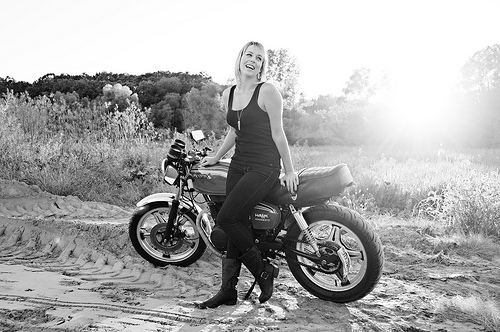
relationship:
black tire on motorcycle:
[285, 201, 383, 303] [127, 128, 384, 304]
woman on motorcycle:
[194, 38, 301, 309] [127, 128, 384, 304]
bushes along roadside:
[1, 82, 176, 195] [0, 178, 499, 330]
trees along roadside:
[1, 47, 498, 129] [0, 178, 499, 330]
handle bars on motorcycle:
[162, 138, 202, 180] [127, 128, 384, 304]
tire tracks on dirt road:
[3, 224, 193, 300] [2, 217, 492, 329]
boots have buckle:
[242, 260, 278, 294] [260, 265, 270, 280]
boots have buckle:
[205, 258, 237, 310] [260, 265, 270, 280]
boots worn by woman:
[242, 260, 278, 294] [204, 34, 304, 314]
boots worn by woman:
[205, 258, 237, 310] [204, 34, 304, 314]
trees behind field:
[5, 71, 227, 132] [287, 99, 497, 204]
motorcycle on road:
[127, 128, 384, 304] [4, 185, 498, 330]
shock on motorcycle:
[288, 206, 320, 260] [127, 128, 384, 304]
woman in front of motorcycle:
[194, 38, 301, 309] [127, 128, 384, 304]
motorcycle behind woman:
[127, 128, 384, 304] [194, 38, 301, 309]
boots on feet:
[192, 259, 243, 310] [195, 260, 282, 310]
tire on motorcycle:
[131, 195, 209, 266] [167, 141, 389, 301]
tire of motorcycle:
[289, 204, 372, 294] [127, 128, 384, 304]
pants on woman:
[216, 164, 276, 251] [183, 39, 299, 305]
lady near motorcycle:
[191, 54, 326, 254] [159, 143, 489, 307]